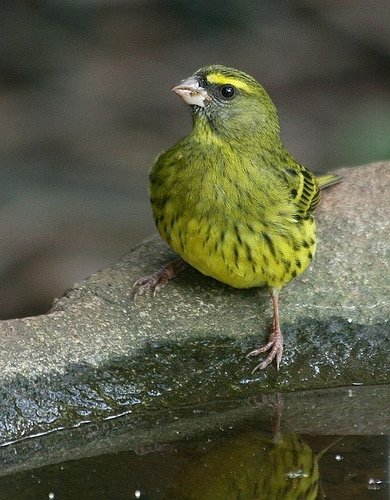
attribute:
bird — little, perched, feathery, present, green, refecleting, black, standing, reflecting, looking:
[132, 64, 345, 374]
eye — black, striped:
[217, 84, 235, 100]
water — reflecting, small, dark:
[0, 384, 389, 497]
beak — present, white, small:
[170, 73, 206, 111]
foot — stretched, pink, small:
[247, 328, 287, 374]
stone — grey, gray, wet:
[1, 161, 390, 446]